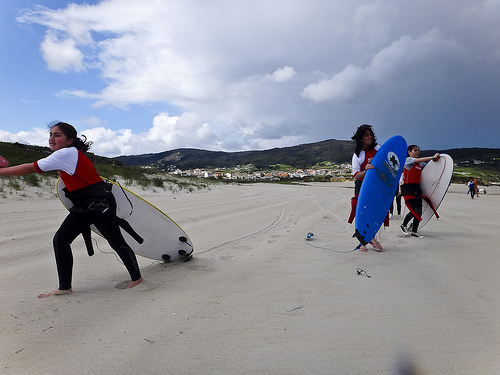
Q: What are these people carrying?
A: Surfboards.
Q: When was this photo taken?
A: During the daytime.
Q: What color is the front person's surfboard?
A: White.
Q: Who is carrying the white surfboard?
A: The girl in the lead.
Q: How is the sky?
A: Mostly cloudy.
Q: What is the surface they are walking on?
A: Sand.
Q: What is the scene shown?
A: Beach scene.